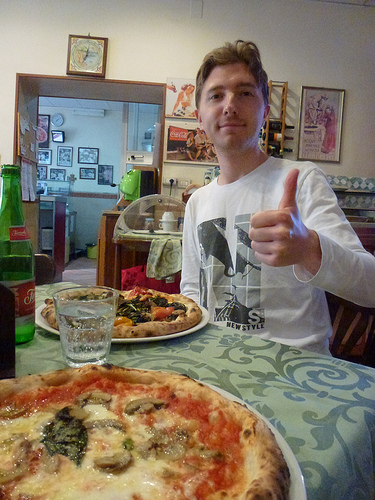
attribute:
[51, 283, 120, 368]
sparking water — sparkling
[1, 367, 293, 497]
pizza — round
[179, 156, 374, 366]
t-shirt — white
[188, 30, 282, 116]
hair — short, brown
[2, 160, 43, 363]
bottle — large, green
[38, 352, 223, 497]
pizza — one, round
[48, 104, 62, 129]
clock — square, wall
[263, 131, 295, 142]
wine bottle — orange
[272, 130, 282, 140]
label — white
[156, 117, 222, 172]
poster — coca cola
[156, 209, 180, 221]
cup — stacked, white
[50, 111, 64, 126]
clock — round, white, wall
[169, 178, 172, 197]
cord — black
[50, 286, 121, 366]
cup — small, crystal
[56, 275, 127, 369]
glass — clear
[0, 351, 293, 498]
pizza — large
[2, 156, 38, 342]
bottle — grenn, sparkling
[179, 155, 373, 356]
shirt — white